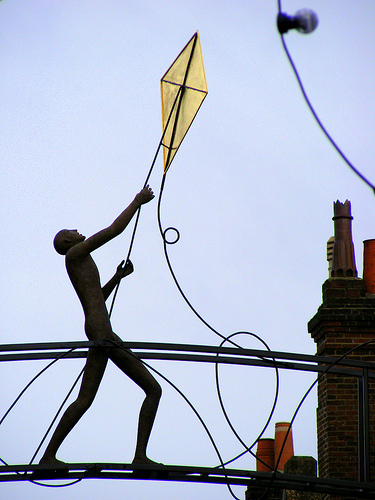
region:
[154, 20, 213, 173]
Yellow kite is flying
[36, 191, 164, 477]
Statue of man with kite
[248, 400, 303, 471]
Chimneys in background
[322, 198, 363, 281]
Chimney is dark brown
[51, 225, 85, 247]
Man's head is bald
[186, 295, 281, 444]
Coil of kite string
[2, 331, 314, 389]
Horizontal metal cable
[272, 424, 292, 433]
White line on chimney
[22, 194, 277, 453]
Sky is gray and blue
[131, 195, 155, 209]
Man's right wrist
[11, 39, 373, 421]
a statue of a man flying a kite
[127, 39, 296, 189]
a statue of a kite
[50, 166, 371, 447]
a statue of a man holding rope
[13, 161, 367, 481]
a statue of a man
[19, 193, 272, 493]
a metal man holding rope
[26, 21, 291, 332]
a metal kite in the air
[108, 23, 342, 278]
a yellow metal kite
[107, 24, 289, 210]
a metal kite that is yellow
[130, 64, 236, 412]
a metal kite with a metal tail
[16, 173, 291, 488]
a metal man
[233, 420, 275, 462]
a chimney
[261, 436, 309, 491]
a chimney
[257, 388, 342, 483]
a chimney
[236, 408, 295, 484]
a chimney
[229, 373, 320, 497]
a chimney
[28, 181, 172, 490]
this is a statue of a man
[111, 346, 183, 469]
the leg of a statues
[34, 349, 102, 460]
the leg of a statues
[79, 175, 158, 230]
the hand of a statues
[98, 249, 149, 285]
the hand of a statues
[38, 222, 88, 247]
the head of a statues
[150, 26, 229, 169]
the kite statue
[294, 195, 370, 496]
this is a building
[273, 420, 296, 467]
this is a yellow tank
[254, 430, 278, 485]
this is a yellow tank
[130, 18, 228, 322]
large white paper kite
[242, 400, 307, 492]
orange factory smoke towers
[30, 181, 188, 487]
statue of a man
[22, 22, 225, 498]
statue of man flying kite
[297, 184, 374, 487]
tall brick building with smokestacks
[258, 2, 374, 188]
long blue cable with light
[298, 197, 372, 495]
large brick tower on building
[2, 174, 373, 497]
metal decoration on entryway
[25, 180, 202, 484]
metal sculpture of man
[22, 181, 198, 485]
statue of man looking up